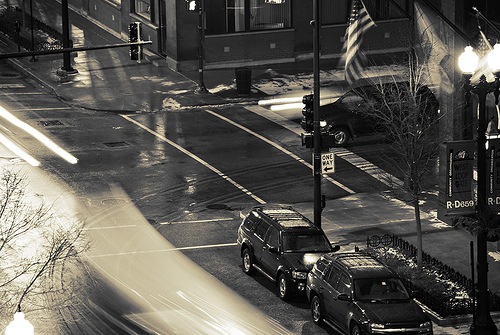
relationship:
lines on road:
[124, 118, 195, 164] [56, 83, 252, 217]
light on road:
[122, 23, 149, 59] [56, 83, 252, 217]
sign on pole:
[317, 151, 348, 180] [20, 48, 71, 63]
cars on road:
[236, 186, 407, 329] [56, 83, 252, 217]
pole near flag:
[20, 48, 71, 63] [337, 2, 384, 82]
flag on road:
[337, 2, 384, 82] [56, 83, 252, 217]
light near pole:
[122, 23, 149, 59] [20, 48, 71, 63]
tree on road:
[368, 74, 441, 236] [56, 83, 252, 217]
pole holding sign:
[20, 48, 71, 63] [317, 151, 348, 180]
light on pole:
[122, 23, 149, 59] [20, 48, 71, 63]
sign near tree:
[317, 151, 348, 180] [368, 74, 441, 236]